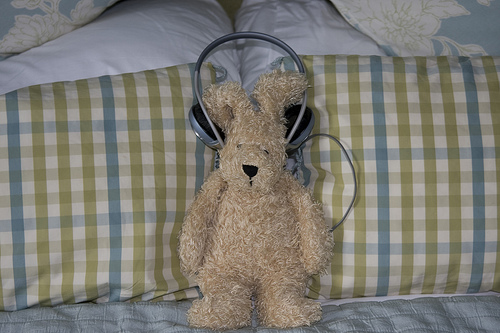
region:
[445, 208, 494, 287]
part of the striped patterned pillow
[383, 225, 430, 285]
part of the striped patterned pillow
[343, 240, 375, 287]
part of the striped patterned pillow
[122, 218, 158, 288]
part of the striped patterned pillow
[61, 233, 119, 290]
part of the striped patterned pillow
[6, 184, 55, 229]
part of the striped patterned pillow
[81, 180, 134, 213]
part of the striped patterned pillow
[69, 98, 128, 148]
part of the striped patterned pillow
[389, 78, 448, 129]
part of the striped patterned pillow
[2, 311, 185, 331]
blanket called a comforter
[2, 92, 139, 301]
pillow case with white, yellow and blue stripes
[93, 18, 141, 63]
white pillow case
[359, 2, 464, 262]
three pillows on left side of bed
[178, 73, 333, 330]
stuffed animals standing on bed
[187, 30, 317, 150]
headphones for the stuffed animal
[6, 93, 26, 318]
Long lines on a pillow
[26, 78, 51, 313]
Long lines on a pillow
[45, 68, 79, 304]
Long lines on a pillow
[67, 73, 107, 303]
Long lines on a pillow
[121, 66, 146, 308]
Long lines on a pillow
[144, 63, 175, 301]
Long lines on a pillow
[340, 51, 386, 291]
Long lines on a pillow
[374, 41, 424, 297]
Long lines on a pillow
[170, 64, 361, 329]
Toy on the bed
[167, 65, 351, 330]
Toy is on the bed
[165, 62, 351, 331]
Rabbit on the bed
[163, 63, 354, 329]
Rabbit is on the bed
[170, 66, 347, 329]
Toy rabbit on the bed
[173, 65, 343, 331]
Toy rabbit is on the bed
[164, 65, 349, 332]
Stuffed rabbit on the bed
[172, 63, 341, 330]
Stuffed rabbit is on the bed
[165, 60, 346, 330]
Stuffed toy on the bed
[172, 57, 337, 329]
Stuffed toy is on the bed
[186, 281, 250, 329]
The foot of the teddy bear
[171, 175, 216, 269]
The arm of the teddy bear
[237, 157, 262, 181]
The nose of the teddy bear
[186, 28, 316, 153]
The teddy bear is wearing ear phones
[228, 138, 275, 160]
The eye's of the teddy bear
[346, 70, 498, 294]
The pillow is plaid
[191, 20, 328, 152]
The headphones are gray and black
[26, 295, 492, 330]
The cover on the bed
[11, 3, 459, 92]
The white pillows on the bed